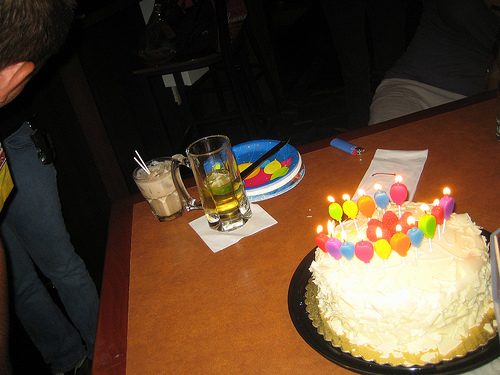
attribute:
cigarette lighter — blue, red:
[328, 137, 364, 157]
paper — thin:
[209, 228, 229, 238]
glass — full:
[128, 149, 188, 223]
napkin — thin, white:
[184, 197, 277, 254]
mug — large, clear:
[168, 141, 267, 243]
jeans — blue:
[2, 121, 102, 371]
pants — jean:
[1, 118, 93, 336]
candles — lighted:
[315, 192, 432, 247]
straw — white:
[126, 145, 163, 182]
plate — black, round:
[272, 277, 304, 331]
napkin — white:
[179, 221, 225, 252]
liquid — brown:
[150, 166, 162, 173]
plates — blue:
[255, 173, 300, 187]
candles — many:
[311, 171, 458, 264]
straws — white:
[131, 148, 150, 177]